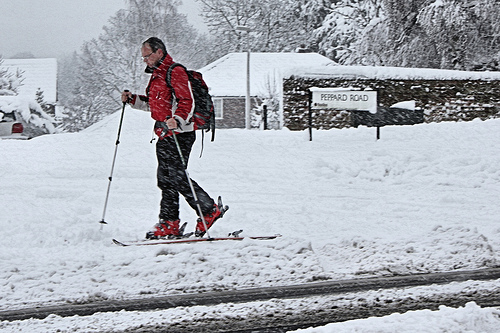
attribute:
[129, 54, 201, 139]
jacket — red 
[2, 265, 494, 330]
cement road — black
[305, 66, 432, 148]
sign — shepard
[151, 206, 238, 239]
boots — red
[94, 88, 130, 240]
ski pole — aluminum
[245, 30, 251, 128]
pole — tall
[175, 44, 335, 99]
roof — covered 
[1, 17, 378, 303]
outside — cold 